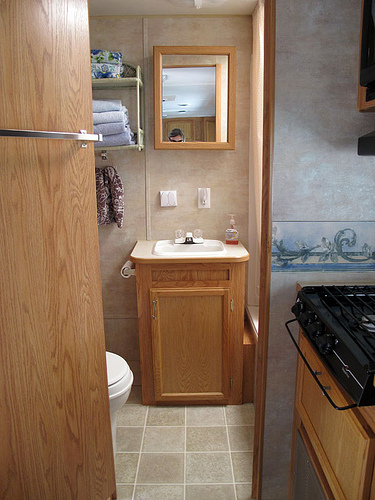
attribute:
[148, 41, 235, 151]
mirror — wooden, framed, bathroom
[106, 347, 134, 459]
toilet — white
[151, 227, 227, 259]
sink — small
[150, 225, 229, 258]
sink — white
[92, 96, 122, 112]
towel — folded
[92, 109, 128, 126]
towel — folded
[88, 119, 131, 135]
towel — folded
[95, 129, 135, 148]
towel — folded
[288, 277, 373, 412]
stove top — black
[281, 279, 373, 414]
stove — black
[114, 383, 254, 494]
floor — brown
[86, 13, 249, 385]
wall — brown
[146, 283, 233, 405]
cupboard — brown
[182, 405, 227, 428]
tile — square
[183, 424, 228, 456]
tile — square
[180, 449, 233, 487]
tile — square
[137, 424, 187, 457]
tile — square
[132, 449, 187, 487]
tile — square